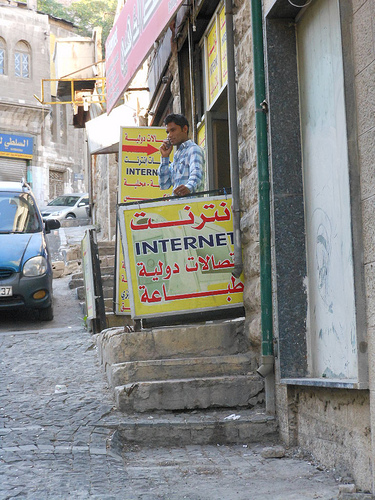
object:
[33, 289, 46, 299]
light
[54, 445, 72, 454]
brick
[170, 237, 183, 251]
letter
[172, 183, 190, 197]
hand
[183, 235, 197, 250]
letter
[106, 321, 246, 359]
stairs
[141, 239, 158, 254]
letter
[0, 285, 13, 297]
plate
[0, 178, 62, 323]
car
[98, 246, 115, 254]
stairs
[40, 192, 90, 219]
car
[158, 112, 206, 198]
man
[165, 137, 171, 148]
phone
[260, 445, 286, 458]
brick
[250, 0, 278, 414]
pipe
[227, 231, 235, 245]
letter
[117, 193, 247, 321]
sign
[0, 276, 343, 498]
brick road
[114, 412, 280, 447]
stairs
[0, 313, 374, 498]
ground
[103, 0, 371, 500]
store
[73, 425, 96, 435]
brick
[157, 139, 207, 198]
shirt